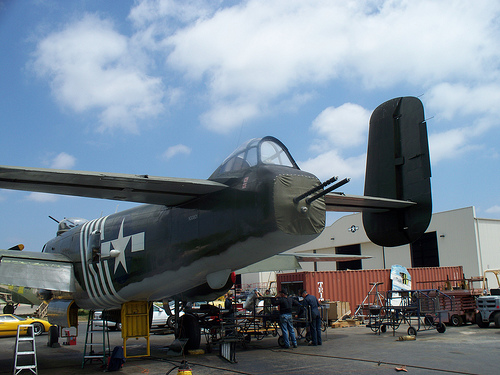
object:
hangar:
[291, 205, 499, 309]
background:
[39, 165, 275, 311]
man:
[294, 289, 322, 346]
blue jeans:
[278, 313, 297, 347]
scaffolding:
[365, 289, 454, 337]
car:
[0, 313, 58, 337]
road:
[0, 320, 499, 375]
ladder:
[11, 324, 42, 375]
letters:
[317, 281, 325, 301]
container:
[276, 265, 465, 321]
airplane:
[0, 95, 435, 360]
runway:
[0, 309, 499, 375]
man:
[270, 288, 307, 349]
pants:
[307, 307, 322, 346]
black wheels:
[407, 326, 418, 336]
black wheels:
[380, 326, 386, 333]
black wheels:
[435, 321, 446, 333]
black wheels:
[449, 314, 462, 327]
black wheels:
[424, 314, 434, 325]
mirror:
[361, 95, 433, 248]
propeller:
[48, 215, 90, 236]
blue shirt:
[302, 294, 322, 315]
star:
[110, 217, 132, 275]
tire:
[27, 322, 45, 337]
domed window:
[218, 135, 301, 175]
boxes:
[323, 301, 351, 320]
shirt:
[271, 297, 307, 315]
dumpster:
[275, 265, 464, 325]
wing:
[0, 166, 228, 207]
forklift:
[415, 269, 499, 329]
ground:
[0, 317, 499, 375]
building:
[235, 205, 500, 317]